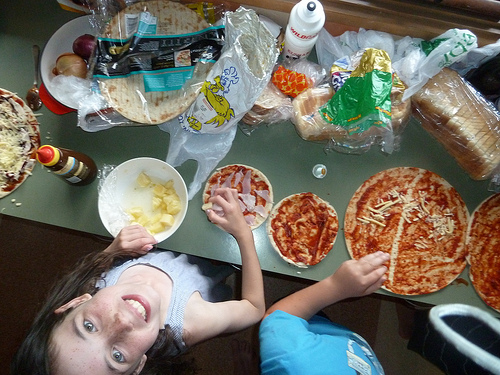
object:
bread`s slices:
[458, 130, 500, 171]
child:
[256, 250, 392, 374]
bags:
[176, 6, 284, 139]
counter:
[0, 0, 500, 320]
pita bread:
[94, 0, 213, 125]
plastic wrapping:
[71, 0, 234, 130]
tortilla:
[201, 162, 274, 232]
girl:
[0, 187, 264, 374]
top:
[93, 250, 241, 362]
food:
[0, 86, 44, 201]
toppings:
[240, 169, 258, 192]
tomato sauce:
[309, 236, 317, 245]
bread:
[472, 158, 500, 180]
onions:
[51, 51, 88, 84]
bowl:
[40, 13, 128, 116]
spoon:
[26, 44, 43, 111]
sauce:
[357, 200, 366, 209]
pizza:
[464, 195, 499, 315]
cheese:
[265, 189, 339, 267]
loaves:
[464, 118, 492, 149]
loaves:
[290, 70, 411, 143]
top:
[259, 308, 388, 374]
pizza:
[343, 164, 471, 296]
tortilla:
[97, 0, 210, 125]